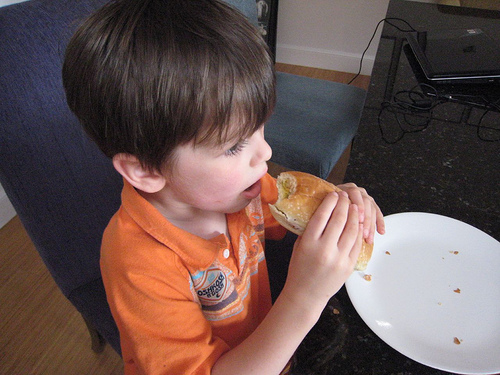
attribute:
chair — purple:
[2, 2, 131, 359]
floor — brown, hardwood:
[5, 304, 48, 369]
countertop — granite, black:
[382, 121, 445, 204]